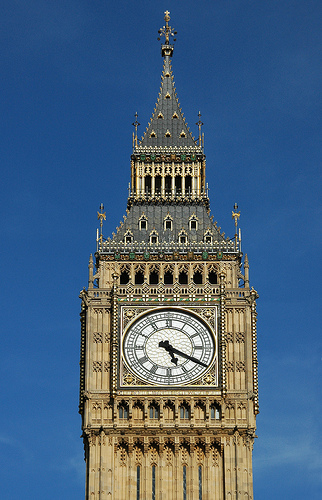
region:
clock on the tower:
[121, 305, 218, 389]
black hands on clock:
[151, 336, 204, 372]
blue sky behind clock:
[6, 362, 64, 415]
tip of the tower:
[142, 8, 179, 65]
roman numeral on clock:
[160, 309, 179, 332]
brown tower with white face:
[55, 252, 274, 409]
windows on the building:
[108, 392, 229, 441]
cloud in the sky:
[269, 420, 313, 469]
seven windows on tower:
[123, 205, 216, 243]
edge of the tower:
[66, 342, 99, 400]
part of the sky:
[233, 30, 265, 75]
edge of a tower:
[242, 469, 256, 494]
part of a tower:
[145, 435, 169, 457]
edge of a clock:
[164, 373, 183, 387]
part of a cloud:
[265, 442, 290, 478]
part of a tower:
[178, 453, 204, 476]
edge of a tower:
[81, 457, 97, 478]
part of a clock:
[164, 365, 179, 384]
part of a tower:
[176, 432, 203, 466]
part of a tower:
[116, 445, 139, 479]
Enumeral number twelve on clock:
[161, 314, 176, 332]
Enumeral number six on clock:
[162, 364, 175, 382]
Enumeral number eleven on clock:
[146, 317, 162, 333]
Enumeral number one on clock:
[178, 319, 189, 333]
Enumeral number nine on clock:
[131, 342, 148, 352]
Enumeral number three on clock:
[189, 342, 206, 351]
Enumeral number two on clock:
[189, 327, 200, 342]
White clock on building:
[113, 294, 226, 389]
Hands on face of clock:
[158, 339, 213, 374]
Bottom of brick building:
[87, 400, 252, 498]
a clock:
[95, 283, 233, 404]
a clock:
[116, 325, 177, 388]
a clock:
[96, 257, 250, 480]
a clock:
[163, 346, 236, 427]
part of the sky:
[73, 44, 107, 89]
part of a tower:
[164, 460, 198, 495]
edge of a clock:
[158, 379, 181, 388]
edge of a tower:
[244, 456, 256, 478]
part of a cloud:
[257, 442, 284, 469]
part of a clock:
[174, 363, 190, 381]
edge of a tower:
[249, 456, 264, 474]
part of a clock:
[158, 369, 169, 380]